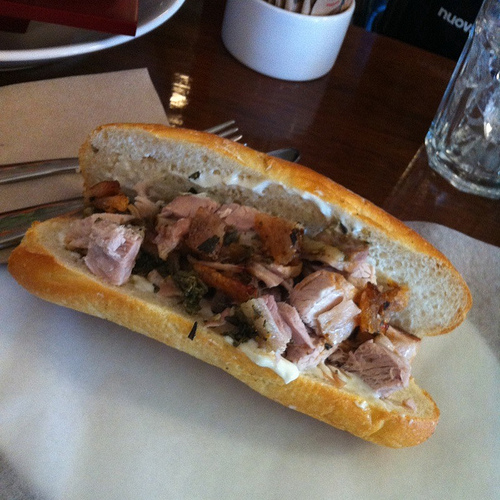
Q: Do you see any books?
A: No, there are no books.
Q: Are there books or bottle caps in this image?
A: No, there are no books or bottle caps.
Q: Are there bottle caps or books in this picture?
A: No, there are no books or bottle caps.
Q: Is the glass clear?
A: Yes, the glass is clear.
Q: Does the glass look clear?
A: Yes, the glass is clear.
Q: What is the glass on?
A: The glass is on the table.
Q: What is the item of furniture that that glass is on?
A: The piece of furniture is a table.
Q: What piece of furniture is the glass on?
A: The glass is on the table.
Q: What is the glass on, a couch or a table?
A: The glass is on a table.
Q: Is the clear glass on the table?
A: Yes, the glass is on the table.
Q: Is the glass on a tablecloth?
A: No, the glass is on the table.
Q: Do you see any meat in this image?
A: Yes, there is meat.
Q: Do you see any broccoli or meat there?
A: Yes, there is meat.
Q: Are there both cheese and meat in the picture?
A: No, there is meat but no cheese.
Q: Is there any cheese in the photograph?
A: No, there is no cheese.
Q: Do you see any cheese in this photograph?
A: No, there is no cheese.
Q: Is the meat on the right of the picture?
A: Yes, the meat is on the right of the image.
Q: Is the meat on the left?
A: No, the meat is on the right of the image.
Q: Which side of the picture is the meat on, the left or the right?
A: The meat is on the right of the image.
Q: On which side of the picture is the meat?
A: The meat is on the right of the image.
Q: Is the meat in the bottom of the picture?
A: Yes, the meat is in the bottom of the image.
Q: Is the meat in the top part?
A: No, the meat is in the bottom of the image.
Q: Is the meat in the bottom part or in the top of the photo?
A: The meat is in the bottom of the image.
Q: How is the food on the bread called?
A: The food is meat.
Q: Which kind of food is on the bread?
A: The food is meat.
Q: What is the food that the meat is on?
A: The food is a bread.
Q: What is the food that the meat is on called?
A: The food is a bread.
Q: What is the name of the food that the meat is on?
A: The food is a bread.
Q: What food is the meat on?
A: The meat is on the bread.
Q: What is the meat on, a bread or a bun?
A: The meat is on a bread.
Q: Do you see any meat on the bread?
A: Yes, there is meat on the bread.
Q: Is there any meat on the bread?
A: Yes, there is meat on the bread.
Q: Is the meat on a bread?
A: Yes, the meat is on a bread.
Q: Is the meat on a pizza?
A: No, the meat is on a bread.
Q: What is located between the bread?
A: The meat is between the bread.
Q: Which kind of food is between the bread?
A: The food is meat.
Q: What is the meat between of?
A: The meat is between the bread.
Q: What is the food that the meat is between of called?
A: The food is a bread.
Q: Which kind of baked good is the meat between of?
A: The meat is between the bread.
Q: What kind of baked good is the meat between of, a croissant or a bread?
A: The meat is between a bread.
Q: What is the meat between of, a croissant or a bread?
A: The meat is between a bread.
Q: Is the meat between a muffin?
A: No, the meat is between the bread.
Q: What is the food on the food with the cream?
A: The food is meat.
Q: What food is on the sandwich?
A: The food is meat.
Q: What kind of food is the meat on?
A: The meat is on the sandwich.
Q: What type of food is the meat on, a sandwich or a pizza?
A: The meat is on a sandwich.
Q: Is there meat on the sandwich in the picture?
A: Yes, there is meat on the sandwich.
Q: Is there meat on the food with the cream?
A: Yes, there is meat on the sandwich.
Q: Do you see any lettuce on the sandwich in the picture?
A: No, there is meat on the sandwich.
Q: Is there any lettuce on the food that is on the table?
A: No, there is meat on the sandwich.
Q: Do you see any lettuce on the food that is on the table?
A: No, there is meat on the sandwich.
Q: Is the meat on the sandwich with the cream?
A: Yes, the meat is on the sandwich.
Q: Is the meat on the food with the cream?
A: Yes, the meat is on the sandwich.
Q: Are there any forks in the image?
A: Yes, there is a fork.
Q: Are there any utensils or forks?
A: Yes, there is a fork.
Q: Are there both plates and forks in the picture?
A: Yes, there are both a fork and a plate.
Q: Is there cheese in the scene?
A: No, there is no cheese.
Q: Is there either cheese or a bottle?
A: No, there are no cheese or bottles.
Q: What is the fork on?
A: The fork is on the table.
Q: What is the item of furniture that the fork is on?
A: The piece of furniture is a table.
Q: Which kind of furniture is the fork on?
A: The fork is on the table.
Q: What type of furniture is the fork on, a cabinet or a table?
A: The fork is on a table.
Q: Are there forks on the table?
A: Yes, there is a fork on the table.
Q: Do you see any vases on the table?
A: No, there is a fork on the table.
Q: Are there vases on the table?
A: No, there is a fork on the table.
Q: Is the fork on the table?
A: Yes, the fork is on the table.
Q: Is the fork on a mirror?
A: No, the fork is on the table.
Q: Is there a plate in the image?
A: Yes, there is a plate.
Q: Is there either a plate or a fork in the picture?
A: Yes, there is a plate.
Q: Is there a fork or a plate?
A: Yes, there is a plate.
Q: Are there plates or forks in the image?
A: Yes, there is a plate.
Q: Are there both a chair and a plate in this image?
A: No, there is a plate but no chairs.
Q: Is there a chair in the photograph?
A: No, there are no chairs.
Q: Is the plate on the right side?
A: No, the plate is on the left of the image.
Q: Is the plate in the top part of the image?
A: Yes, the plate is in the top of the image.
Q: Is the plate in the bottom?
A: No, the plate is in the top of the image.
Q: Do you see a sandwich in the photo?
A: Yes, there is a sandwich.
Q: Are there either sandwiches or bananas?
A: Yes, there is a sandwich.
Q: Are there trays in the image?
A: No, there are no trays.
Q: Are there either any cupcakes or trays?
A: No, there are no trays or cupcakes.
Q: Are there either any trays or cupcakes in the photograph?
A: No, there are no trays or cupcakes.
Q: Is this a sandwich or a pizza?
A: This is a sandwich.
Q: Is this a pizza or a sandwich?
A: This is a sandwich.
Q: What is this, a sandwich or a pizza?
A: This is a sandwich.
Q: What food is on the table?
A: The food is a sandwich.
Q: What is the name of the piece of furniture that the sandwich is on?
A: The piece of furniture is a table.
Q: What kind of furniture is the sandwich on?
A: The sandwich is on the table.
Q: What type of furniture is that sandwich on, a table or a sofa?
A: The sandwich is on a table.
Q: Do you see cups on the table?
A: No, there is a sandwich on the table.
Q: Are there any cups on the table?
A: No, there is a sandwich on the table.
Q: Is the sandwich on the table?
A: Yes, the sandwich is on the table.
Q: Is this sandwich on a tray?
A: No, the sandwich is on the table.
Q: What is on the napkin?
A: The sandwich is on the napkin.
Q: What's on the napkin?
A: The sandwich is on the napkin.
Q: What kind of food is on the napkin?
A: The food is a sandwich.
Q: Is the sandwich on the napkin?
A: Yes, the sandwich is on the napkin.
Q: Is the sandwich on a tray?
A: No, the sandwich is on the napkin.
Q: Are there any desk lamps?
A: No, there are no desk lamps.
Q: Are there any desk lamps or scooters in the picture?
A: No, there are no desk lamps or scooters.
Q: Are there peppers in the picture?
A: No, there are no peppers.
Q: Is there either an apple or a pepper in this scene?
A: No, there are no peppers or apples.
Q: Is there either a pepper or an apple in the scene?
A: No, there are no peppers or apples.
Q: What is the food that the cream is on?
A: The food is a bread.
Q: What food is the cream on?
A: The cream is on the bread.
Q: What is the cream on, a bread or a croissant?
A: The cream is on a bread.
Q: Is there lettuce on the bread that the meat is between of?
A: No, there is cream on the bread.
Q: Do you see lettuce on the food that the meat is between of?
A: No, there is cream on the bread.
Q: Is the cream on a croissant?
A: No, the cream is on the bread.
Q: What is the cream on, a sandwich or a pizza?
A: The cream is on a sandwich.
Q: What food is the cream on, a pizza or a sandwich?
A: The cream is on a sandwich.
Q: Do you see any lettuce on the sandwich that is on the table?
A: No, there is cream on the sandwich.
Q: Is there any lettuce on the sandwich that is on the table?
A: No, there is cream on the sandwich.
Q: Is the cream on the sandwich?
A: Yes, the cream is on the sandwich.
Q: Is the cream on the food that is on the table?
A: Yes, the cream is on the sandwich.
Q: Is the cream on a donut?
A: No, the cream is on the sandwich.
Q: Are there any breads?
A: Yes, there is a bread.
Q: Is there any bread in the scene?
A: Yes, there is a bread.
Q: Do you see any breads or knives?
A: Yes, there is a bread.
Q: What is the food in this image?
A: The food is a bread.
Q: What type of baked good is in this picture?
A: The baked good is a bread.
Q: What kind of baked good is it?
A: The food is a bread.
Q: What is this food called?
A: This is a bread.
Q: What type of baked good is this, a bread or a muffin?
A: This is a bread.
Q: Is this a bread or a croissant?
A: This is a bread.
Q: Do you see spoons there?
A: Yes, there is a spoon.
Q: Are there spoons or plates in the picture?
A: Yes, there is a spoon.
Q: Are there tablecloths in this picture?
A: No, there are no tablecloths.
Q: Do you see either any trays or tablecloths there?
A: No, there are no tablecloths or trays.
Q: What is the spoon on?
A: The spoon is on the table.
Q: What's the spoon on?
A: The spoon is on the table.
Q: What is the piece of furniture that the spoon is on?
A: The piece of furniture is a table.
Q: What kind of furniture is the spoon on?
A: The spoon is on the table.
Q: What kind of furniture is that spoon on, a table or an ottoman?
A: The spoon is on a table.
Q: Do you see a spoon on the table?
A: Yes, there is a spoon on the table.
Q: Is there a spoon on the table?
A: Yes, there is a spoon on the table.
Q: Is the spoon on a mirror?
A: No, the spoon is on the table.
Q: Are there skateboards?
A: No, there are no skateboards.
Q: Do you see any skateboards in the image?
A: No, there are no skateboards.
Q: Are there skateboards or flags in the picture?
A: No, there are no skateboards or flags.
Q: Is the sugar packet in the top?
A: Yes, the sugar packet is in the top of the image.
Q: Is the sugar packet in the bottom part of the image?
A: No, the sugar packet is in the top of the image.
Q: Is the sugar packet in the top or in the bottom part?
A: The sugar packet is in the top of the image.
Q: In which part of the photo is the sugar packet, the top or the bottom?
A: The sugar packet is in the top of the image.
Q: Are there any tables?
A: Yes, there is a table.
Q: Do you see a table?
A: Yes, there is a table.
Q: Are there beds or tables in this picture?
A: Yes, there is a table.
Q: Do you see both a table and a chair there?
A: No, there is a table but no chairs.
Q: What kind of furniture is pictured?
A: The furniture is a table.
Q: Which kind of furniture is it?
A: The piece of furniture is a table.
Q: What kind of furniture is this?
A: This is a table.